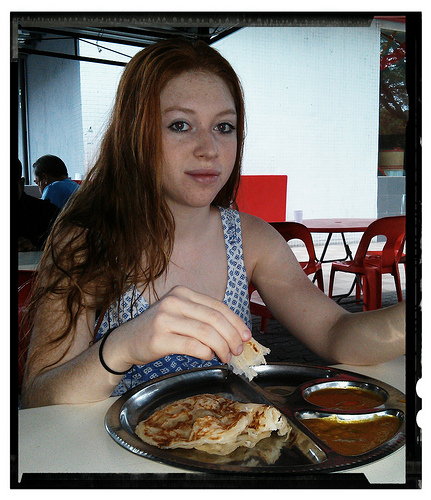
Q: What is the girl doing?
A: Eating.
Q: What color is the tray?
A: Silver.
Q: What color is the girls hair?
A: Brown.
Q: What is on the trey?
A: Food.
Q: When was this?
A: Daytime.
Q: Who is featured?
A: A girl.